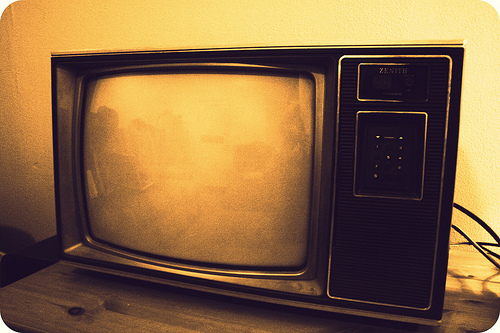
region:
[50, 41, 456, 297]
that is a television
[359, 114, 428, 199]
the speaker of the tv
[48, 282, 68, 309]
part of the table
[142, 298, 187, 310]
part of the table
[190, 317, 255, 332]
part of the table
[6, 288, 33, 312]
part of the table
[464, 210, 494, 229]
that is a cable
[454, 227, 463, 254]
that is acable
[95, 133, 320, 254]
this is a television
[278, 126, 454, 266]
these are buttons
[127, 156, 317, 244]
this is a monitor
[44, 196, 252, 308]
this is a screen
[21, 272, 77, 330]
this is a desk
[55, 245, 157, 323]
this is made of wood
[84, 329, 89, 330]
the wood is dark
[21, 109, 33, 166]
the wall has nothing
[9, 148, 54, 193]
the wall is bare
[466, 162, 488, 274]
these are dark cables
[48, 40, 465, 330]
An old style big mostly black tv.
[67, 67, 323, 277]
Large popped out glass tv screen that is off.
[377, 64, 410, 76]
The word ZENITH on a tv.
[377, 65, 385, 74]
A Z in ZENITH.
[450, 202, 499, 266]
Two wires coming off the back right of the tv.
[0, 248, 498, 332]
A wooden stand a tv is on.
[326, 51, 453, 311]
Thin silver trim around a tv speaker and buttons.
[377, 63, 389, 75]
A ZE in ZENITH.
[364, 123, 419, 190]
The black and white buttons that control the tv.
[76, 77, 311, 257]
Reflections of the room in the tv glass.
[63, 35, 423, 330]
the tv is old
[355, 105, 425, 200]
the television has buttons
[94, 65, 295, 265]
the screen is small in size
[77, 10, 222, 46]
the wall is orange in colour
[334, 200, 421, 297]
the speaker is black in colur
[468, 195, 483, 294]
the cables are black in colour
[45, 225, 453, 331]
the television is on the table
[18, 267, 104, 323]
the table is brown in colour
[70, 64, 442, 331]
the tv is off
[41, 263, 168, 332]
the table is smooth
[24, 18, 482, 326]
a tv is on a table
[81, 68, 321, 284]
the screen on the tv shows a reflection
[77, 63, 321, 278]
the tv is in a storage room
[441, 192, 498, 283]
wires are coming from the back of the tv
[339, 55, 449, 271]
a control panel is on the tv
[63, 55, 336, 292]
the frame of the screen is black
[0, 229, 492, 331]
the tv is on a wooden table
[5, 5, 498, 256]
a wall of drywall is behind the tv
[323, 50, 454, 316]
the controls on the tv have a silver trim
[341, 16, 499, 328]
sunlight is coming in on the side of the tv